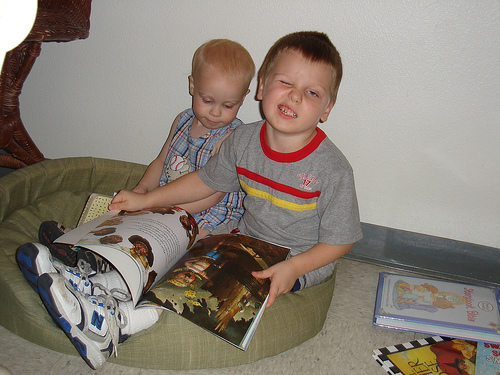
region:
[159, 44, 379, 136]
two faces of kids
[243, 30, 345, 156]
a white face of a kid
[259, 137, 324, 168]
small neck of the kid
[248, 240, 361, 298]
hand of the kid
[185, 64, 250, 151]
a boy looking at kid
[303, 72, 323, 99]
eye of a kid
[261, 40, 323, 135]
a cute boy teasing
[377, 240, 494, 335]
a big book placed aside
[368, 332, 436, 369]
a yellow object placed down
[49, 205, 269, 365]
a book book with nice designs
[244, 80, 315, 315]
a kid in grey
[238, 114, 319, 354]
a kid in grey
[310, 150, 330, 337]
a kid in grey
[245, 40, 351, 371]
a kid in grey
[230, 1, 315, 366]
a kid in grey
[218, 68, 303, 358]
a kid in grey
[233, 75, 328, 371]
a kid in grey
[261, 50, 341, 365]
a kid in grey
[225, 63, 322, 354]
a kid in grey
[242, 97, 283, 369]
a kid in grey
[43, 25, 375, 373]
two boys reading a book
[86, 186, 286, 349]
an opened book with images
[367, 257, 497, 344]
a children's book on the floor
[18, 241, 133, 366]
a boy wearing white and blue sneakers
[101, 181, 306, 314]
a boy holding a book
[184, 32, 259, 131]
boy with blond hair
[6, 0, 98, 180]
wooden leg of a table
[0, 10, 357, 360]
two boys sitting on a pouf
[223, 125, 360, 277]
boy wearing a gray shirt with red and yellow lines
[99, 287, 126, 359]
white shoelaces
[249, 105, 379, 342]
a kid in grey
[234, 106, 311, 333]
a kid in grey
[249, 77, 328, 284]
a kid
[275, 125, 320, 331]
a kid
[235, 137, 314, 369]
a kid